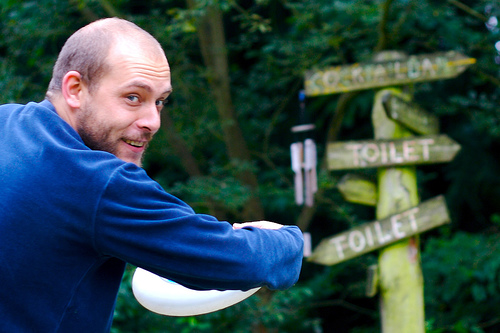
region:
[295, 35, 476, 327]
A wooden sign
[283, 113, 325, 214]
The wind chimes are still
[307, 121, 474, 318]
The toilets are in both directions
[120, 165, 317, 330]
Getting ready to throw a frisbee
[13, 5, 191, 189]
The man is smiling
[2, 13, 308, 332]
The man is getting ready to throw the frisbee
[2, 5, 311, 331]
The man just caught the frisbee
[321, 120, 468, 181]
The toilet is to the right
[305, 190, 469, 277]
The toilet is down the hill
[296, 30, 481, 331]
A wooden sign post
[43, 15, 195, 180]
a man with a balding head.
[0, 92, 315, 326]
A blue shirt.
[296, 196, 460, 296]
a street sign on a post.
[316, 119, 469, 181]
a toilet sign on a post.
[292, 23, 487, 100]
a sign on a post.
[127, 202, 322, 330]
a white tray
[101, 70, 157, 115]
the right eye of a man.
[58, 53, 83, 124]
a right ear on a man.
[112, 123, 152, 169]
a man with a mouth.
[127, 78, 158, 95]
a right eye brow.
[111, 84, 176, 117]
the mans eyes are blue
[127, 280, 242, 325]
the frisbee is white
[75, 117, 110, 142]
the man has a beard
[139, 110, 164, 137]
the man has a nose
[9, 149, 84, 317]
the shirt is blue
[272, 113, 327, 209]
the wind chimes are hanging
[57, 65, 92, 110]
the man has an ear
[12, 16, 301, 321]
the man is throwing a frisbee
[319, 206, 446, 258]
the word toilet is in white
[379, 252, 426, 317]
the pole is wooden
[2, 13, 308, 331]
nearly bald man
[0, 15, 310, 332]
man getting ready to throw a frisbee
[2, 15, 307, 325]
man dressed in blue long sleeved shirt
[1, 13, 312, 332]
nearly bald man with blue shirt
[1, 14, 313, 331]
man in blue shirt getting ready to throw frisbee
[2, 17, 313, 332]
man in blue shirt getting ready to throw white frisbee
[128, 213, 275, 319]
mans white frisbee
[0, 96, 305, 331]
mans blue shirt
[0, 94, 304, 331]
mans long sleeved blue shirt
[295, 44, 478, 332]
whimsical sign on a wooden post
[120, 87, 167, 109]
Pair of blue eyes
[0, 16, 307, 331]
Man getting ready to throw a frisbee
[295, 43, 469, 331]
Three wooden directional arrows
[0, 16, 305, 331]
Man wearing a blue long sleeved shirt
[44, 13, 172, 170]
Balding head of hair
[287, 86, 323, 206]
Silver chimes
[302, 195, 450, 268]
Wooden toilet sign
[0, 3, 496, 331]
Man outside playing with a frisbee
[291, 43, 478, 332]
Wood pole supporting signs and chimes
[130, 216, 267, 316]
Small white frisbee